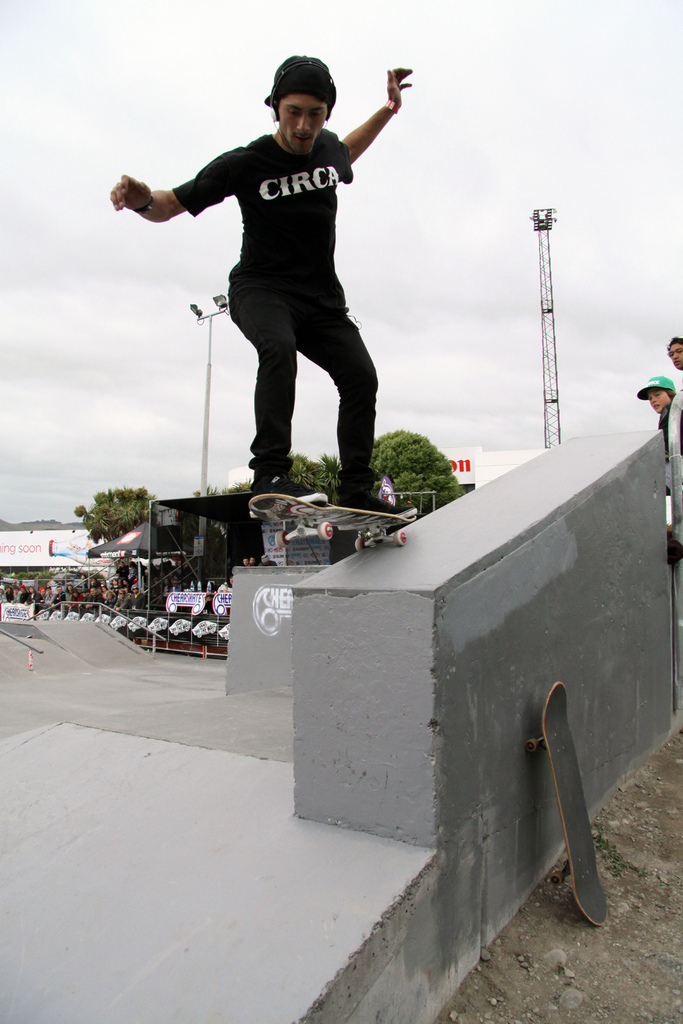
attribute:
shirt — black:
[165, 126, 369, 317]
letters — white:
[252, 574, 294, 642]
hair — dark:
[640, 341, 661, 365]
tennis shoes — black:
[243, 456, 425, 519]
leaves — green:
[98, 501, 137, 524]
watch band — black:
[137, 187, 153, 223]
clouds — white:
[22, 36, 183, 181]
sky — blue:
[15, 9, 645, 282]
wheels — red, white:
[264, 510, 413, 554]